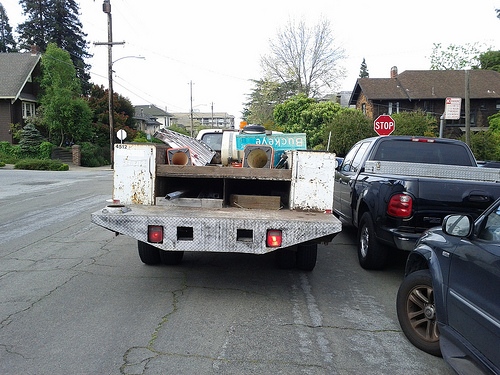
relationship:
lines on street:
[287, 281, 334, 354] [10, 172, 414, 367]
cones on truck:
[167, 146, 276, 172] [87, 109, 346, 274]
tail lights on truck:
[127, 219, 292, 257] [87, 125, 348, 274]